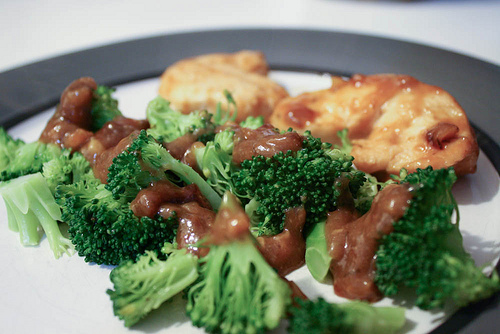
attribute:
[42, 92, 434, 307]
sauce — brown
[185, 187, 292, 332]
broccoli — green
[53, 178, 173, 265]
broccoli — green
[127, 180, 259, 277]
sauce — brown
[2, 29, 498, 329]
food — stacked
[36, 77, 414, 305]
brown sauce — brown 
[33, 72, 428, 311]
sauce — brown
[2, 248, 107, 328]
plate — white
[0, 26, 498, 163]
edge — grey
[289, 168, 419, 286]
sauce — brown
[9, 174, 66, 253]
broccoli stem — green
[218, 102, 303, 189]
sauce — brown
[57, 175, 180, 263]
broccoli — green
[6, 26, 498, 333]
plate — white, full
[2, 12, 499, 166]
table — white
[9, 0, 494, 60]
table — white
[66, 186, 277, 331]
broccoli — green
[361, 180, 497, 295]
broccoli — raw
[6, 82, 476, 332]
broccoli — raw 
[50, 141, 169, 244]
broccoli — green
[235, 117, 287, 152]
sauce — brown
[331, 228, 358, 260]
sauce — brown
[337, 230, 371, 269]
sauce — brown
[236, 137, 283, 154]
sauce — brown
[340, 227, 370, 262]
sauce — brown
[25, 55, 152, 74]
edge — grey